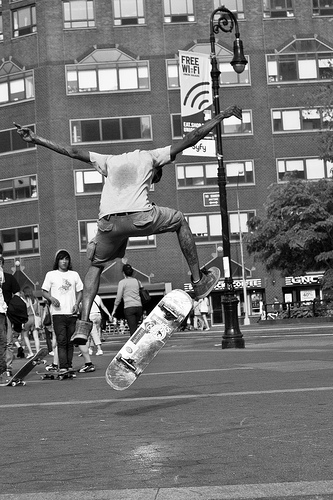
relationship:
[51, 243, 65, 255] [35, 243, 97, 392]
cap on man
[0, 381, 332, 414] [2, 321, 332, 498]
line on ground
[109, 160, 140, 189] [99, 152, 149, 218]
sweat on back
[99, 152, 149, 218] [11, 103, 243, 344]
back of man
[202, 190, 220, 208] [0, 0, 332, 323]
sign on building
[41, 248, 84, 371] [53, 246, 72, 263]
guy wearing cap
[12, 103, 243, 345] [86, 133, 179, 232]
man wearing shirt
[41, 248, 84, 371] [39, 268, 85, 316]
guy wearing shirt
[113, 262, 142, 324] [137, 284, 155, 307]
woman holding purse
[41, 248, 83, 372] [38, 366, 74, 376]
guy on a skateboard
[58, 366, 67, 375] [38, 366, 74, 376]
foot on a skateboard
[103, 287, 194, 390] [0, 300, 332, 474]
skateboard in air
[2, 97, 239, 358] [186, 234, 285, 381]
man in air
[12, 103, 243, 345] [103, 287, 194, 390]
man doing trick on skateboard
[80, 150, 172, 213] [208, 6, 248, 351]
shirt on lamp post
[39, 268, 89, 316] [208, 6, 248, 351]
shirt on lamp post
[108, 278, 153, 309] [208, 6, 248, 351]
shirt on lamp post